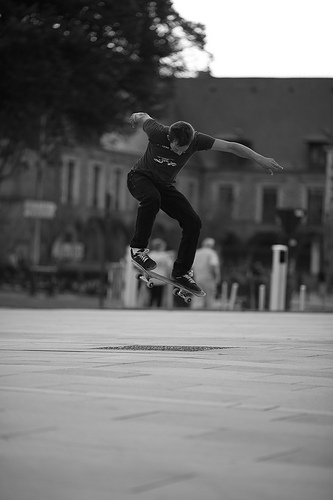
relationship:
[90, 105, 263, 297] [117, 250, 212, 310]
guy riding skateboard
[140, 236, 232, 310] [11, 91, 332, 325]
two people walking in park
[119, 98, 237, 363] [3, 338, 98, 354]
skateboarder has shadow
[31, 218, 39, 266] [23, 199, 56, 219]
pole in signboard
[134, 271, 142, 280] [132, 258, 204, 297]
wheel of skateboard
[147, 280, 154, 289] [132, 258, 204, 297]
wheel of skateboard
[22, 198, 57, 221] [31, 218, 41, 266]
sign on pole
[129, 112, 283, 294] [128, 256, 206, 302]
guy on a skateboard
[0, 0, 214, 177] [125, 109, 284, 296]
trees above skater